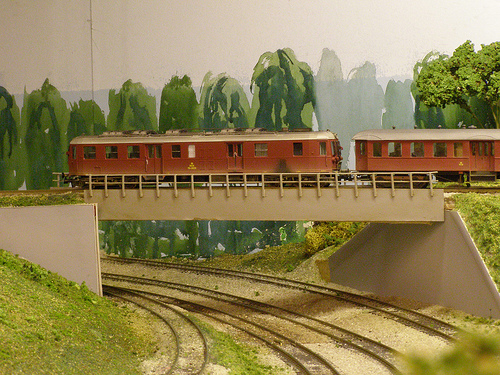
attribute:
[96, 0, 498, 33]
sky — blue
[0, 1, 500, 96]
sky — blue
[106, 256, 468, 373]
train tracks — brown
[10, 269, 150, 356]
grass — real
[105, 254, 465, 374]
railroad track — miniature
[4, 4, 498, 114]
sky — blue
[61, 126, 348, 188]
train car — red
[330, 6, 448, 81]
sky — blue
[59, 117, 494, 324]
bridge — brown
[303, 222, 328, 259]
bush — small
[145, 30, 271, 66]
sky — blue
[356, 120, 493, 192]
car — red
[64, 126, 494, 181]
miniature train — displayed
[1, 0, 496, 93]
cloud — white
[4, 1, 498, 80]
cloud — white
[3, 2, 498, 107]
cloud — white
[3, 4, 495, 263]
backdrop — painted